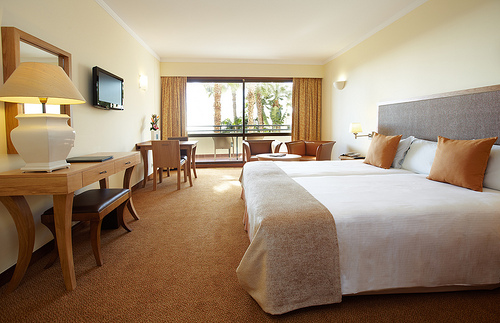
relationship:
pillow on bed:
[429, 135, 469, 179] [300, 165, 392, 240]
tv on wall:
[92, 68, 131, 118] [89, 19, 142, 60]